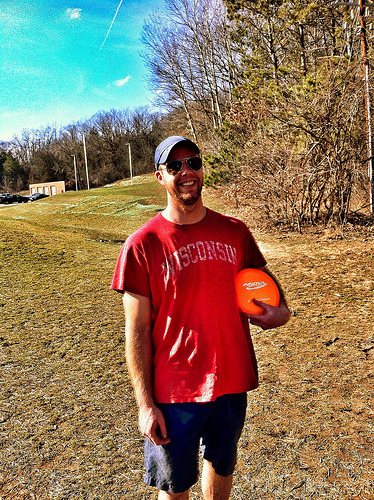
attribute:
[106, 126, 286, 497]
man — standing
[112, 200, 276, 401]
shirt — red, wisconsin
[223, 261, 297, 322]
frisbee — orange, round, white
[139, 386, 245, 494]
shorts — blue, navy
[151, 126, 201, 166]
cap — blue, navy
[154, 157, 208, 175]
sunglasses — black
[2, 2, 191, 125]
sky — blue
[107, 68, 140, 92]
cloud — white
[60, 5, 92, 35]
cloud — white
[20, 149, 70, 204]
building — brown, brick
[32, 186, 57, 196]
doors — white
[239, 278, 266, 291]
words — white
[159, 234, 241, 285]
words — faded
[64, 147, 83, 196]
pole — metal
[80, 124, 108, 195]
pole — metal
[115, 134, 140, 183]
pole — metal